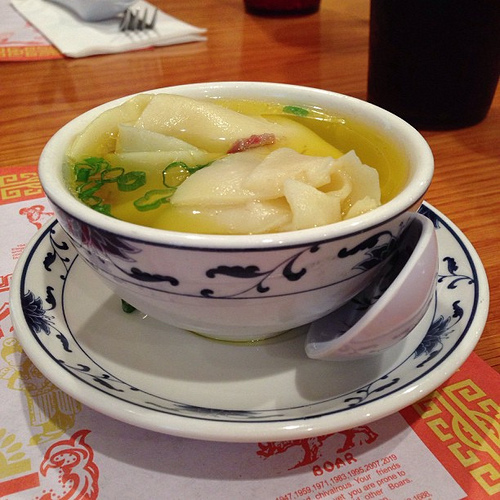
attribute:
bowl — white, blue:
[369, 234, 438, 324]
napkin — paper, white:
[7, 1, 213, 61]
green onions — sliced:
[71, 158, 167, 213]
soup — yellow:
[65, 92, 417, 239]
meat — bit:
[226, 132, 273, 153]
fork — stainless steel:
[118, 6, 156, 31]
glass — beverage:
[394, 17, 484, 88]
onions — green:
[79, 164, 132, 196]